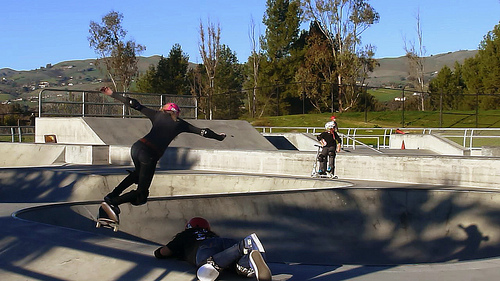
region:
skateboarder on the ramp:
[80, 98, 200, 215]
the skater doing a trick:
[89, 71, 231, 230]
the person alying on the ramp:
[142, 202, 281, 279]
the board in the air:
[90, 207, 121, 235]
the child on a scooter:
[305, 117, 347, 185]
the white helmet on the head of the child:
[322, 118, 340, 133]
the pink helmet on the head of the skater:
[159, 97, 180, 115]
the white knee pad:
[195, 262, 225, 280]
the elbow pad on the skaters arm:
[123, 93, 142, 112]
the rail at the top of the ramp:
[34, 84, 89, 116]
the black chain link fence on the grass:
[370, 82, 497, 132]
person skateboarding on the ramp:
[75, 70, 218, 208]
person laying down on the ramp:
[152, 212, 282, 279]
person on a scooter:
[299, 115, 340, 187]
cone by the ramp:
[395, 135, 409, 155]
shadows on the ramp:
[436, 216, 493, 263]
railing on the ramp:
[35, 82, 94, 115]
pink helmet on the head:
[159, 101, 186, 114]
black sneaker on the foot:
[95, 190, 125, 220]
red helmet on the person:
[181, 215, 209, 229]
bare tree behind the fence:
[402, 1, 437, 101]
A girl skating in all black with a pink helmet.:
[98, 84, 226, 224]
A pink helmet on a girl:
[161, 102, 178, 116]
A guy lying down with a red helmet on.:
[155, 215, 272, 280]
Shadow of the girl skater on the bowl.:
[453, 220, 491, 260]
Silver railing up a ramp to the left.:
[36, 86, 198, 118]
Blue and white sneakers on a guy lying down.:
[239, 231, 269, 280]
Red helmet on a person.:
[327, 114, 336, 121]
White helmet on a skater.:
[323, 119, 336, 133]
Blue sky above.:
[1, 0, 499, 63]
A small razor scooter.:
[311, 142, 337, 180]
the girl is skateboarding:
[75, 80, 195, 240]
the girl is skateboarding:
[55, 63, 197, 277]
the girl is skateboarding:
[89, 64, 193, 258]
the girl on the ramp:
[137, 199, 267, 279]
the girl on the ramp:
[151, 206, 256, 276]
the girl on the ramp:
[161, 199, 271, 279]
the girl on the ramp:
[142, 194, 247, 279]